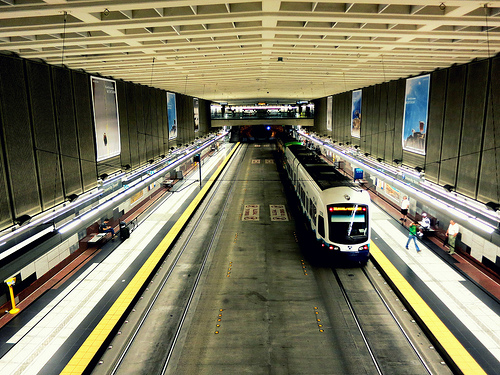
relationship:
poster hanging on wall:
[91, 72, 124, 163] [0, 49, 223, 225]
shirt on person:
[418, 215, 435, 227] [414, 210, 431, 236]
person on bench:
[414, 210, 431, 236] [398, 204, 440, 244]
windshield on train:
[323, 202, 369, 244] [274, 136, 375, 268]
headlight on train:
[325, 241, 340, 254] [274, 136, 375, 268]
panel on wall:
[18, 57, 73, 210] [4, 39, 225, 198]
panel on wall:
[71, 75, 97, 193] [0, 49, 223, 225]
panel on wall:
[48, 61, 83, 197] [0, 49, 223, 225]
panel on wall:
[25, 56, 62, 207] [0, 49, 223, 225]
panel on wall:
[452, 63, 488, 199] [307, 55, 487, 205]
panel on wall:
[425, 68, 447, 186] [307, 55, 487, 205]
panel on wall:
[95, 84, 136, 165] [3, 55, 215, 206]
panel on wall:
[123, 80, 141, 169] [0, 49, 223, 225]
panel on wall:
[140, 86, 157, 160] [7, 66, 206, 203]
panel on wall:
[118, 77, 170, 166] [3, 51, 212, 243]